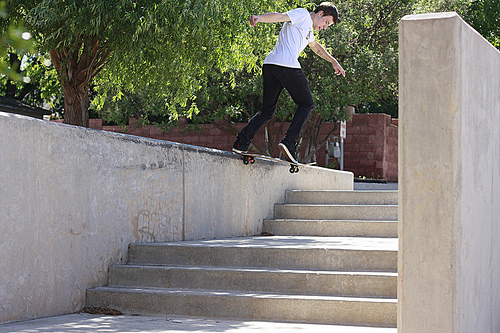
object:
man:
[230, 0, 350, 167]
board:
[239, 150, 317, 173]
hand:
[246, 16, 265, 23]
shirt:
[261, 6, 318, 69]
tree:
[0, 0, 334, 135]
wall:
[398, 12, 500, 333]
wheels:
[289, 165, 297, 174]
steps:
[285, 189, 400, 206]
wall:
[0, 111, 355, 323]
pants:
[232, 63, 318, 151]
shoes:
[277, 142, 300, 164]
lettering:
[342, 125, 346, 129]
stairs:
[264, 190, 399, 238]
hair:
[309, 1, 343, 26]